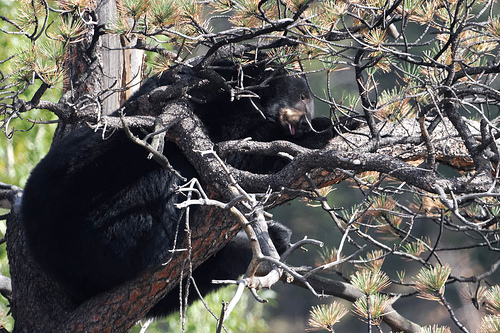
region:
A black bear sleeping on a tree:
[11, 33, 359, 324]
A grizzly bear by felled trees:
[1, 35, 372, 327]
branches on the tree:
[207, 123, 427, 323]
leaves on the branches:
[5, 56, 46, 166]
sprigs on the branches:
[319, 205, 431, 328]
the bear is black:
[71, 85, 243, 311]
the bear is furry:
[54, 86, 236, 309]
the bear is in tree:
[60, 62, 330, 312]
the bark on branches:
[193, 111, 360, 309]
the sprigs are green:
[323, 151, 458, 321]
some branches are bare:
[208, 151, 315, 324]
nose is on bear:
[251, 58, 326, 140]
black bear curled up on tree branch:
[6, 5, 495, 327]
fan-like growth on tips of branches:
[293, 247, 450, 331]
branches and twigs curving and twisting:
[133, 23, 485, 277]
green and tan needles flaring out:
[343, 268, 393, 294]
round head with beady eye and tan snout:
[260, 68, 319, 136]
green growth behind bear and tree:
[2, 2, 267, 329]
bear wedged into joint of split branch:
[4, 41, 316, 331]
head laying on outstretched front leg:
[248, 53, 381, 140]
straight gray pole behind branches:
[73, 1, 140, 136]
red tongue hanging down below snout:
[271, 97, 311, 139]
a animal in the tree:
[55, 25, 358, 289]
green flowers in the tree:
[292, 220, 441, 332]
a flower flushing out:
[306, 290, 341, 331]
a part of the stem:
[200, 119, 411, 181]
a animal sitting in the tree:
[13, 30, 360, 285]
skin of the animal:
[68, 141, 168, 255]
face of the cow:
[186, 27, 479, 247]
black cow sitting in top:
[21, 43, 377, 304]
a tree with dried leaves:
[118, 15, 461, 206]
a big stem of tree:
[29, 10, 146, 107]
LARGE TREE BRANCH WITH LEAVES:
[24, 8, 499, 256]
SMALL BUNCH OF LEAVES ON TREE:
[314, 304, 345, 329]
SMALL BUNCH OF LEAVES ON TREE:
[348, 273, 388, 293]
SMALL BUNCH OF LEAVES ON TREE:
[358, 301, 378, 313]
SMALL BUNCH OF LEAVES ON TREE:
[360, 244, 387, 264]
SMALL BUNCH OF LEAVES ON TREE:
[420, 265, 441, 293]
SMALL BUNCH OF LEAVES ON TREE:
[477, 281, 495, 305]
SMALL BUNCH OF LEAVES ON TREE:
[480, 316, 497, 331]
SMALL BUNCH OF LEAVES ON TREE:
[376, 76, 402, 112]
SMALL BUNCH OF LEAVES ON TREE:
[13, 49, 48, 84]